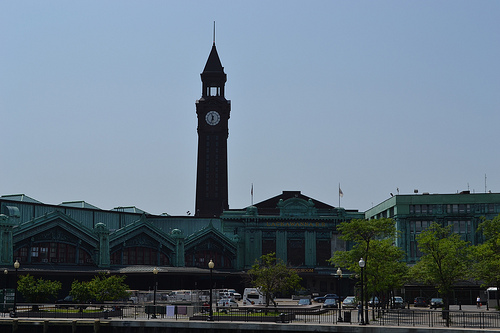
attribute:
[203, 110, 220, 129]
clock — round, white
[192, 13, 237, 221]
tower — brown, tall, black, white, dark, large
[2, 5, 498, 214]
sky — clear, blue, black, big, wide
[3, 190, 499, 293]
buildings — short, small, brown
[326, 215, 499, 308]
trees — thin, green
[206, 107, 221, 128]
clock face — white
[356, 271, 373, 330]
post — metal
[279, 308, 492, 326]
railing — metal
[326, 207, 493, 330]
trees — green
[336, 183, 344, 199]
flag — white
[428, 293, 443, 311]
car — black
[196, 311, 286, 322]
grass — green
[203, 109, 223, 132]
clock face — round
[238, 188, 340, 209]
roof — black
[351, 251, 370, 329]
lamp post — tall, black